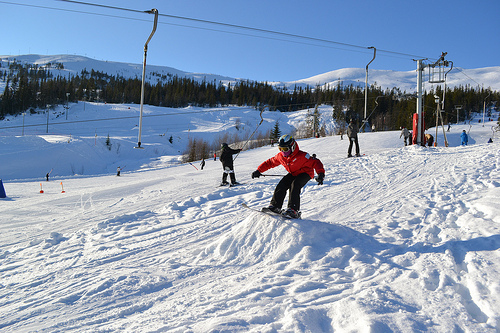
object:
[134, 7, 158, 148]
pole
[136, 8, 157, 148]
part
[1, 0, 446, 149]
ski lift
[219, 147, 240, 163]
jacket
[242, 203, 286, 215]
skis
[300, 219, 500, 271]
shadow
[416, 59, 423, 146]
metal post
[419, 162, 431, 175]
ground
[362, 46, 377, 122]
pole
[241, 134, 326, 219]
snowboarder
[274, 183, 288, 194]
knee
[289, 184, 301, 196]
knee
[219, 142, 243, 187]
person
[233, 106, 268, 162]
pole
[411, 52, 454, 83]
lift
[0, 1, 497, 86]
sky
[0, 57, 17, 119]
trees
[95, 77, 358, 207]
slope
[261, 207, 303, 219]
skis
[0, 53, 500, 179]
mountain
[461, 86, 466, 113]
tree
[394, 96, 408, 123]
tree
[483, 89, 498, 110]
tree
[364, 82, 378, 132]
tree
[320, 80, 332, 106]
tree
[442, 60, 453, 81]
poles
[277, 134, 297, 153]
helmet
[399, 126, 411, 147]
person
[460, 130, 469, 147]
person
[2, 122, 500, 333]
park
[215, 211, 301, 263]
ramp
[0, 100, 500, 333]
snow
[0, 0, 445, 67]
wire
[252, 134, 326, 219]
man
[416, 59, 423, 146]
pole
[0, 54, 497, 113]
range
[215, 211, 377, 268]
mound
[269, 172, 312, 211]
pants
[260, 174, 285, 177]
pole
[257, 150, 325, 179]
jacket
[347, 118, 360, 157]
man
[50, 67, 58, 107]
tree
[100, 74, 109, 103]
tree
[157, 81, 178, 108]
tree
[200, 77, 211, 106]
tree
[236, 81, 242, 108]
tree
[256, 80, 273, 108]
tree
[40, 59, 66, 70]
tree